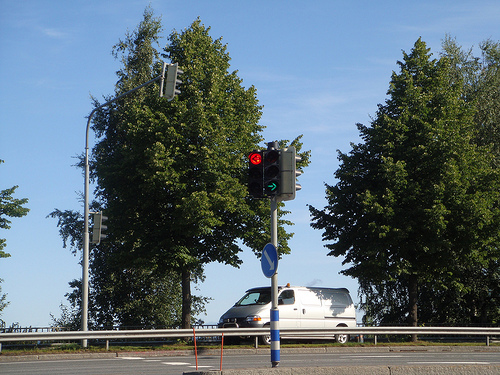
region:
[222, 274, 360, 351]
a gray van on the road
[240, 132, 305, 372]
two traffic lights on a pole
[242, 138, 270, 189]
traffic light is in red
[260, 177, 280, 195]
a green arrow on traffic light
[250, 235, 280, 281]
the sign is blue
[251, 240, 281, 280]
sign has a white arrow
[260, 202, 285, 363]
pole has blue stripes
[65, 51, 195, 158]
a traffic light on a pole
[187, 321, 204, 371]
thin orange sticks on road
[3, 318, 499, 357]
a gray rail on side the road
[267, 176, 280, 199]
There is a green arrow here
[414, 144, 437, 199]
There are green trees here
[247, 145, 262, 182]
There is a red stoplight here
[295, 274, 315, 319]
There is a white van visible here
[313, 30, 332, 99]
There is a light-blue sky in the distance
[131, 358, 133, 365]
There is a black patch of asphalt here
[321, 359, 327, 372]
There is a curb that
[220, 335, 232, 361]
There are orange, metal rods here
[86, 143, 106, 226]
There is a silver pole visible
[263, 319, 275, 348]
There is a black tire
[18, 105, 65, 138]
a clear blue sky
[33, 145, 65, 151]
a clear blue sky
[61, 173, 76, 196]
a clear blue sky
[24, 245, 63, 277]
a clear blue sky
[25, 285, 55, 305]
a clear blue sky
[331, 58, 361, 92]
a clear blue sky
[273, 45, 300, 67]
a clear blue sky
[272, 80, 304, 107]
a clear blue sky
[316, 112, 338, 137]
a clear blue sky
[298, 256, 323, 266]
a clear blue sky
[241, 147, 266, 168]
red traffic light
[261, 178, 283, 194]
green arrow on traffic light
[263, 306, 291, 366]
blue and white striped portion of traffic light support pole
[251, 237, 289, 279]
blue and white traffic sign on pole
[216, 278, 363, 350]
white van parked in grass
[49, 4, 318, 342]
tree on side of street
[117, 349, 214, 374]
white lines drawn on street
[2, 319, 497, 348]
metal street barrier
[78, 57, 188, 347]
traffic light on tall metal pole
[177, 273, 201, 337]
brown tree trunk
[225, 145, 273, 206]
traffic light is red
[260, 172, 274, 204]
traffic light is green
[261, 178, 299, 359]
grey and blue pole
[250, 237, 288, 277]
blue and white sign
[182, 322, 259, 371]
orange sticks near road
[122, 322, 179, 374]
white lines on road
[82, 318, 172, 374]
road is light grey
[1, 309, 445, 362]
metal guardrail near road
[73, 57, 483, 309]
green trees behind road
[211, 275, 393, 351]
white van behind rail